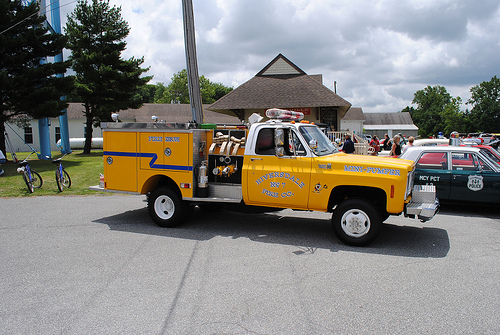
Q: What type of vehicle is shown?
A: Fire truck.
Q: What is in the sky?
A: Clouds.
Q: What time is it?
A: Afternoon.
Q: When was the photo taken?
A: During the daytime.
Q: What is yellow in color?
A: The truck.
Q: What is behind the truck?
A: Grass.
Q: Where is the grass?
A: Behind the truck.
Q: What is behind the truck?
A: Building?.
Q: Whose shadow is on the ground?
A: The trucks.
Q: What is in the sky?
A: Clouds.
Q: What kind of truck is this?
A: Fire.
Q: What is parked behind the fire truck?
A: Bicycles.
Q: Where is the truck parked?
A: In the street.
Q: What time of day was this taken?
A: Afternoon.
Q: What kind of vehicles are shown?
A: Emergency vehicles.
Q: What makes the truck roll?
A: Wheels.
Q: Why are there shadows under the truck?
A: The sun is out.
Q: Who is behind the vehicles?
A: The people.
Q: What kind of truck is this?
A: A fire truck.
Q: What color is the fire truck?
A: Yellow.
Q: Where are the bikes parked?
A: On the lawn.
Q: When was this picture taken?
A: Afternoon.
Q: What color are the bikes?
A: Blue.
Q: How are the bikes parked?
A: Standing with kickstands down.